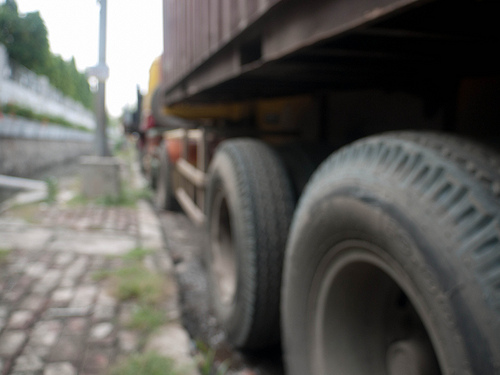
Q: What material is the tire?
A: Rubber.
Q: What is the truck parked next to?
A: A sidewalk.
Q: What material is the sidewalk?
A: Brick.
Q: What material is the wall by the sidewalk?
A: Brick.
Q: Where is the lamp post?
A: On the sidewalk.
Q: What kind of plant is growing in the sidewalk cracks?
A: Weeds.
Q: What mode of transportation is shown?
A: Truck.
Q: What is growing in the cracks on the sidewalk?
A: Grass and weeds.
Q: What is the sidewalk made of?
A: Brick.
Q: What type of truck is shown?
A: Tractor trailer.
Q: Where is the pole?
A: On the sidewalk.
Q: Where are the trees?
A: Left side of the sidewalk.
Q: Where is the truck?
A: Next to the curb.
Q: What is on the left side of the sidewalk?
A: Brick wall.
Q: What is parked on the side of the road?
A: A large truck.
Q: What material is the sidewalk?
A: Brick.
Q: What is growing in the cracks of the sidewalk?
A: Grass.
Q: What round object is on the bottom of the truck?
A: Wheels.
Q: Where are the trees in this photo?
A: Left of the sidewalk.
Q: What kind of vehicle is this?
A: A truck.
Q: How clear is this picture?
A: It's blurry.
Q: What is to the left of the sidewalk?
A: Fence and trees.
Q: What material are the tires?
A: Rubber.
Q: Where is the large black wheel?
A: On the vehicle.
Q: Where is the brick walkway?
A: Beside the street.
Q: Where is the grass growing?
A: Through the brick walkway.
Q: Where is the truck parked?
A: On the side of the street.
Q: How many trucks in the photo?
A: One.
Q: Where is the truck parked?
A: Beside the curb.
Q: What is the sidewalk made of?
A: Bricks.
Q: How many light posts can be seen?
A: One.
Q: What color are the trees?
A: Green.